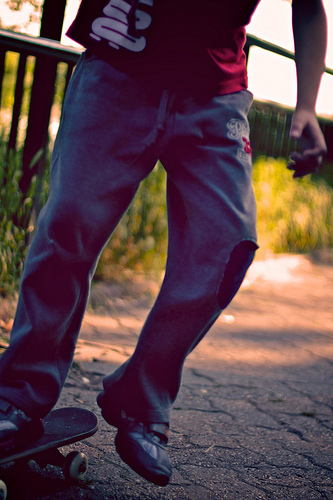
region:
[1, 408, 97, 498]
black skateboard with white wheels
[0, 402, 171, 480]
black tennis shoes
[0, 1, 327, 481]
person with one foot on a skateboard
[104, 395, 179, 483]
foot that is off the skateboard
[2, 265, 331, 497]
cracked black pavement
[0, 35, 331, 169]
wooden fence behind the skateboarder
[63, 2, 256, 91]
the skateboarder's red t-shirt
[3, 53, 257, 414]
the skateboarder's gray sweatpants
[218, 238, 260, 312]
knee patch on the sweatpants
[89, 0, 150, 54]
white text on the t-shirt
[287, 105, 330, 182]
the hand of a boy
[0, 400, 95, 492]
part of a black skateboard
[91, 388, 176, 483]
part of a boy's black shoe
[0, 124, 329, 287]
a tall section of grass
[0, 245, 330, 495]
a portion of a driveway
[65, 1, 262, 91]
part of a boy's red shirt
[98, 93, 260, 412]
the leg of a boy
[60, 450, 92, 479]
a white skateboard wheel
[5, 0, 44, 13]
a portion of green tree leaves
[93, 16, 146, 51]
a white capital letter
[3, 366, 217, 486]
Person is skateboarding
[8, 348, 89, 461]
Right foot is on the skateboard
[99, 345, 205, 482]
Left foot is in the air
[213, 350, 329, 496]
Skateboarding on cement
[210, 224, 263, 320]
Blue pad on the man's knee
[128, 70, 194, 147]
Drawstring on the sweats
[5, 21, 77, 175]
Fence behind boy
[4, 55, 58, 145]
Sun shining through the fence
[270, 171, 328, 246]
Tall grass next to fence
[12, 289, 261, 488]
a close up shot of a skateboarder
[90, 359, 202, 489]
he is wearing dark blue tennis shoes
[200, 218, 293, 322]
a patch on his pants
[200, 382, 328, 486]
cracked pavement beneath the skater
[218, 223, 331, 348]
the sun shining in the background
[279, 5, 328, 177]
the skater's arm is in the shot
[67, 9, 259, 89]
he wearing a maroon shirt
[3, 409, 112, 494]
he has a dark colored skateboard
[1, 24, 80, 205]
a fence behind the skater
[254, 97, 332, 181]
a black fence in the area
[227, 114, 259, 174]
logo on a pair of pants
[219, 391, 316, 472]
cracked and weathers asphalt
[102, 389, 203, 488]
black shoe on a person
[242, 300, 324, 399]
dappled sunlight and shadows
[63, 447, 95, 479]
back wheel of a skateboard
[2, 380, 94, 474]
foot on a skateboard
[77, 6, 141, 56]
logo on a shirt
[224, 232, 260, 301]
patch on the knee of a pair of pants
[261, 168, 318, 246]
sunight on bushes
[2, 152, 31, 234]
green foliage behind a skateboarder